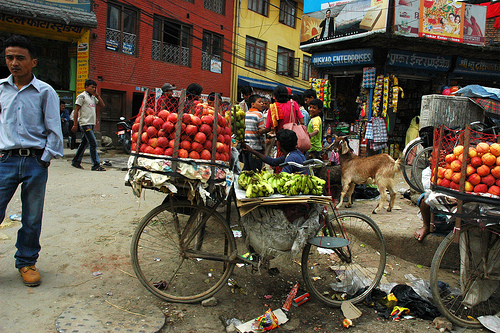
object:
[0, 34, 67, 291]
man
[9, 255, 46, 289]
left foot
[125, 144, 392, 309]
bicycle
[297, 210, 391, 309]
front wheel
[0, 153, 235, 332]
road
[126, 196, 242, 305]
rear wheel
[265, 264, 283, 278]
foot pedal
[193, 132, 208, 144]
apples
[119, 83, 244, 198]
bicycle basket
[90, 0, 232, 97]
house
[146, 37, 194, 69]
balcony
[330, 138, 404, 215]
goat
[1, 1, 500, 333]
market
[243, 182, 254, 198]
bananas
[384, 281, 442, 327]
trash bag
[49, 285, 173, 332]
manhole cover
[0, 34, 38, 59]
mans hair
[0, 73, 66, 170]
shirt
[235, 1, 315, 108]
building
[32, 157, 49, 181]
hand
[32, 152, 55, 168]
pant pocket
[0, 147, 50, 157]
belt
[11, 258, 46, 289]
boots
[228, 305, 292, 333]
trash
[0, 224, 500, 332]
street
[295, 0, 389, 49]
signs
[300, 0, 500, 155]
building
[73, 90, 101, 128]
shirt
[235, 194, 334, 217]
cardboard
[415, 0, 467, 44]
sign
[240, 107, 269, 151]
shirt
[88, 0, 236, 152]
building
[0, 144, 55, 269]
jeans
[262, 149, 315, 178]
shirt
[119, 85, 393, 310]
bicycle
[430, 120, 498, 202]
cart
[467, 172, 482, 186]
peaches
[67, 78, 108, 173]
man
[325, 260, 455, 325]
garbage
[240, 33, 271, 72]
windows